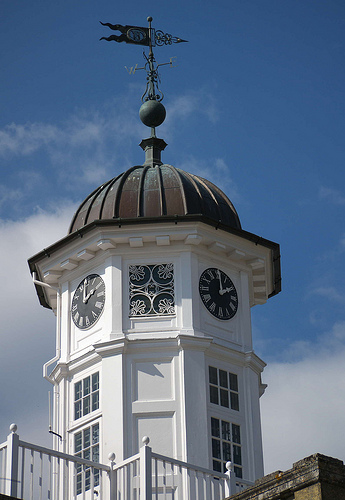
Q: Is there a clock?
A: Yes, there is a clock.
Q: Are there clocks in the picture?
A: Yes, there is a clock.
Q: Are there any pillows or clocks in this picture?
A: Yes, there is a clock.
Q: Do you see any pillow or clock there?
A: Yes, there is a clock.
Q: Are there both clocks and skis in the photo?
A: No, there is a clock but no skis.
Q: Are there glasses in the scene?
A: No, there are no glasses.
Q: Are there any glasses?
A: No, there are no glasses.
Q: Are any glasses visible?
A: No, there are no glasses.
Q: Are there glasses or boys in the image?
A: No, there are no glasses or boys.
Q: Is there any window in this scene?
A: Yes, there is a window.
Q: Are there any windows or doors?
A: Yes, there is a window.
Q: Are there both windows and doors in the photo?
A: No, there is a window but no doors.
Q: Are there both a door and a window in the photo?
A: No, there is a window but no doors.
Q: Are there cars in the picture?
A: No, there are no cars.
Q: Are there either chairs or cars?
A: No, there are no cars or chairs.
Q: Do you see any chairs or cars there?
A: No, there are no cars or chairs.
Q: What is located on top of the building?
A: The window is on top of the building.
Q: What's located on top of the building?
A: The window is on top of the building.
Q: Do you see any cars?
A: No, there are no cars.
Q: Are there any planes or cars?
A: No, there are no cars or planes.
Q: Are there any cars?
A: No, there are no cars.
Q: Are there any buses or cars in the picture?
A: No, there are no cars or buses.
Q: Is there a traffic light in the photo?
A: No, there are no traffic lights.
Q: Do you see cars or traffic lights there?
A: No, there are no traffic lights or cars.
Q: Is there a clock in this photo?
A: Yes, there is a clock.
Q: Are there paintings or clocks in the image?
A: Yes, there is a clock.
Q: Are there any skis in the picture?
A: No, there are no skis.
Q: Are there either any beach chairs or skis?
A: No, there are no skis or beach chairs.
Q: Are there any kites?
A: No, there are no kites.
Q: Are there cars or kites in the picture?
A: No, there are no kites or cars.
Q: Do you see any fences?
A: Yes, there is a fence.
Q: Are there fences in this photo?
A: Yes, there is a fence.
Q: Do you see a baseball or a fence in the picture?
A: Yes, there is a fence.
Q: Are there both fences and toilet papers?
A: No, there is a fence but no toilet papers.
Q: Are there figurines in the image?
A: No, there are no figurines.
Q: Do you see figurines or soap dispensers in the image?
A: No, there are no figurines or soap dispensers.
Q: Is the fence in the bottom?
A: Yes, the fence is in the bottom of the image.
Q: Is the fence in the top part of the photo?
A: No, the fence is in the bottom of the image.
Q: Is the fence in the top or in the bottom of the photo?
A: The fence is in the bottom of the image.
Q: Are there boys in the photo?
A: No, there are no boys.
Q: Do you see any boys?
A: No, there are no boys.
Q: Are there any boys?
A: No, there are no boys.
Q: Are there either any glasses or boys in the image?
A: No, there are no boys or glasses.